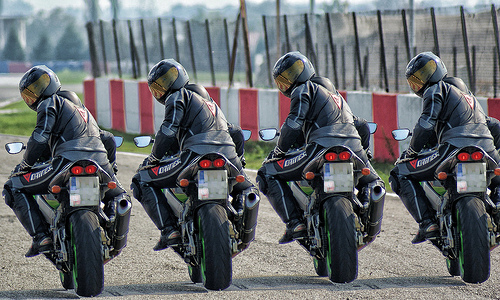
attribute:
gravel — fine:
[126, 257, 179, 298]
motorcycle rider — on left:
[6, 60, 136, 297]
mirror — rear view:
[232, 112, 277, 149]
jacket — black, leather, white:
[271, 76, 373, 153]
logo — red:
[327, 91, 344, 109]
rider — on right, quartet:
[385, 48, 496, 247]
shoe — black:
[22, 236, 54, 261]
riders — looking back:
[8, 69, 124, 253]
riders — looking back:
[134, 59, 254, 253]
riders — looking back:
[261, 52, 381, 240]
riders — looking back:
[394, 50, 496, 242]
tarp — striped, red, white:
[78, 62, 498, 184]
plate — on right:
[427, 148, 499, 228]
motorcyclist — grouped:
[390, 56, 497, 244]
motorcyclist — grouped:
[258, 49, 379, 241]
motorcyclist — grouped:
[129, 57, 249, 251]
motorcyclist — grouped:
[4, 64, 126, 257]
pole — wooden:
[374, 12, 393, 93]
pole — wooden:
[320, 12, 341, 85]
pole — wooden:
[221, 17, 235, 80]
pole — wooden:
[202, 17, 220, 84]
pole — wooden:
[96, 18, 111, 75]